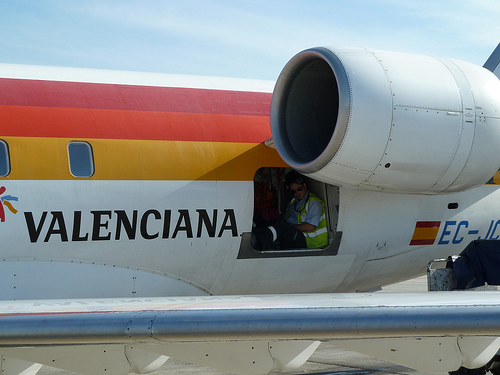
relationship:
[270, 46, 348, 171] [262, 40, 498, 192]
ring on engine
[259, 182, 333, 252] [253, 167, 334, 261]
man squeezed in a hole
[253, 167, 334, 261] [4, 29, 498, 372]
hole on plane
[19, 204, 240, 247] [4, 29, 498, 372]
valencia on side of plane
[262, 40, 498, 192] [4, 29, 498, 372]
engine of plane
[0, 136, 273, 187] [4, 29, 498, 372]
striple on plane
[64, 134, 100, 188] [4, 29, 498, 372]
window on side of plane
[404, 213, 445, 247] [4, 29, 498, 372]
box on plane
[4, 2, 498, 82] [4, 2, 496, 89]
sky with clouds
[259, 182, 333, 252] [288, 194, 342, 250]
man wearing a vest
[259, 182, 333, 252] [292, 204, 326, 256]
man wearing a vest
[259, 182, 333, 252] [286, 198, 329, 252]
man wearing a vest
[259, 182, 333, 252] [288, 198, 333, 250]
man wearing a vest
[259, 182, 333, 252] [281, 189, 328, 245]
man wearing a vest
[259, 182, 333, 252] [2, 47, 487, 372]
man sitting in an airplane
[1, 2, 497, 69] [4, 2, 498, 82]
clouds in sky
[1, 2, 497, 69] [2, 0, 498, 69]
clouds in sky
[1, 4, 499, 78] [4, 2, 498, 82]
clouds in sky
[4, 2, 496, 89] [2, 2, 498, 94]
clouds in sky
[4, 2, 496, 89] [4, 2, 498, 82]
clouds in sky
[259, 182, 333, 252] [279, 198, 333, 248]
man wearing vest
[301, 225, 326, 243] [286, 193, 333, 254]
stripe on vest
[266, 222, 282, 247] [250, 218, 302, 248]
stripe on pants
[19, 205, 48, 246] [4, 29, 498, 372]
v on plane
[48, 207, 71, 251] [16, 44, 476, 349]
letter on plane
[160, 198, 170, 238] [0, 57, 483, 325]
letter on plane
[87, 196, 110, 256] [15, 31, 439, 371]
letter on plane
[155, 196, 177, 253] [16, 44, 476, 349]
letter on plane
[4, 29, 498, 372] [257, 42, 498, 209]
plane has engine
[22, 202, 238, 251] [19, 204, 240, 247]
word says valencia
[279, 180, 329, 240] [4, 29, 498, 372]
crew member in plane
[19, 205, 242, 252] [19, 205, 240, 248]
text says valenciana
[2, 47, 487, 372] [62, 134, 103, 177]
airplane has window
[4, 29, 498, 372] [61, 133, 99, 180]
plane has window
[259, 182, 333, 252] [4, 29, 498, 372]
man in plane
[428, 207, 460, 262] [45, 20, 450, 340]
e on plane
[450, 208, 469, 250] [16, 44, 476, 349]
c on plane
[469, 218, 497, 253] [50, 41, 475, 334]
j on plane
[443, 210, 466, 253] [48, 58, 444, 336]
e on plane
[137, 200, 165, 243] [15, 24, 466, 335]
c on plane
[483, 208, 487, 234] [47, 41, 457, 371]
j on plane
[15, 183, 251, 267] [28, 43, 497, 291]
letters on plane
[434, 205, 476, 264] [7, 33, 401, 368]
letters on plane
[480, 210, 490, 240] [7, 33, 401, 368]
numbers on plane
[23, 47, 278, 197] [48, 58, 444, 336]
striple on plane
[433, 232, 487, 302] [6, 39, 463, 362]
baggage cart near plane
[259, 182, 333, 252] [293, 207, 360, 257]
man with bag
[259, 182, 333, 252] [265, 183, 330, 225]
man wearing shirt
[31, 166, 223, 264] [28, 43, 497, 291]
sign on plane